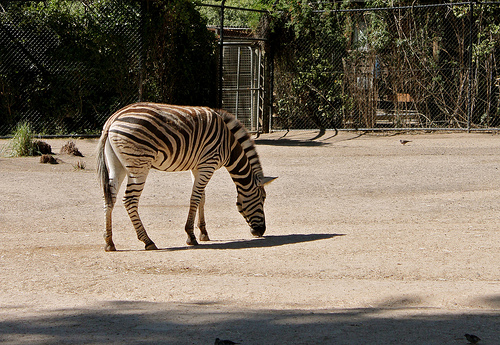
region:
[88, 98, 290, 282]
zebra on the sand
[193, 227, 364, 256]
shadow of the zebra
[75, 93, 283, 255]
the zebra is striped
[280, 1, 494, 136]
the chain link fence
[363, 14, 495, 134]
vines behind the fence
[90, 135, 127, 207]
the tail of the zebra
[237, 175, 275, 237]
the head of the zebra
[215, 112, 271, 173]
the mane of the zebra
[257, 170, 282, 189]
the ear of the zebra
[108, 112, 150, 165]
rump of zebra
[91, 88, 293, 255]
This is a zebra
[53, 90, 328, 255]
The zebra is eating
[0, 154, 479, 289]
The zebra is standing on gravel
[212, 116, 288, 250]
The zebra's neck is craned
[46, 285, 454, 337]
There are shadows on the ground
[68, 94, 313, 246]
Only the right side of the zebra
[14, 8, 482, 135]
There is a fence around the zebra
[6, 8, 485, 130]
The fence is made of wire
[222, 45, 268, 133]
This is the gate to the fence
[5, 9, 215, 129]
Green bushes behind the fence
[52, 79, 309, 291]
zebra is sniffing the ground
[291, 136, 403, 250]
the ground is paved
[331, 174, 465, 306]
the ground is paved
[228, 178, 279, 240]
head of a zebra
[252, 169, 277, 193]
ear of a zebra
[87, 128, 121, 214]
tail of a zebra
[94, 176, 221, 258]
legs of a zebra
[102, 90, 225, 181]
body of a zebra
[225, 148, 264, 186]
neck of a zebra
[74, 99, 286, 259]
a zebra standing on ground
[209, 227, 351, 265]
shadows of a zebra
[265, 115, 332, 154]
shadows on the ground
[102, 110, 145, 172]
the butt of a zebra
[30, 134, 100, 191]
dirt on the ground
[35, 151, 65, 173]
dirt on the ground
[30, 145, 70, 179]
dirt on the ground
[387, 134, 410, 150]
a small bird on the ground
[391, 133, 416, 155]
a small bird on the ground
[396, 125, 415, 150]
a small bird on the ground